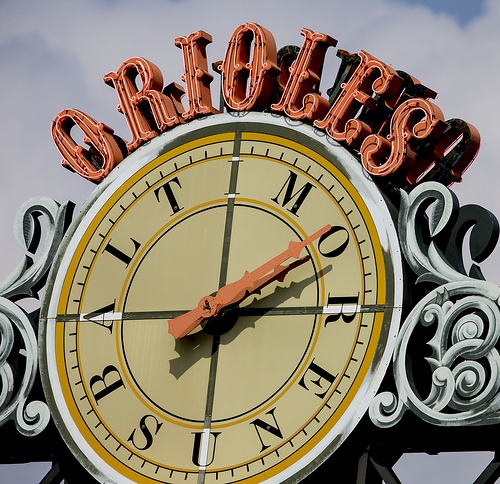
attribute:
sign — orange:
[21, 13, 470, 257]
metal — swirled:
[352, 184, 498, 436]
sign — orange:
[54, 17, 448, 190]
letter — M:
[270, 167, 320, 215]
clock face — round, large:
[25, 42, 429, 476]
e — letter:
[293, 356, 343, 411]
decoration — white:
[372, 179, 495, 430]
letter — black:
[146, 172, 192, 217]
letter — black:
[267, 166, 317, 221]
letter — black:
[315, 291, 365, 323]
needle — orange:
[171, 222, 333, 344]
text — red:
[49, 19, 476, 193]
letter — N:
[247, 405, 294, 466]